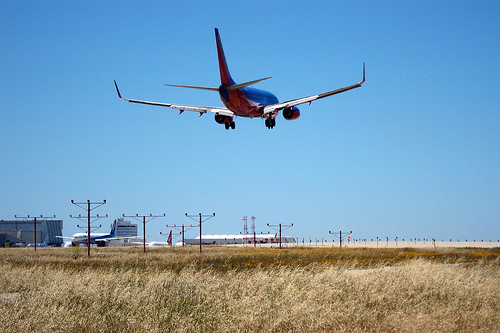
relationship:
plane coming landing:
[107, 26, 367, 131] [21, 251, 299, 281]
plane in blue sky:
[64, 19, 399, 140] [1, 0, 494, 232]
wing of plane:
[100, 60, 374, 124] [98, 24, 373, 151]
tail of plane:
[191, 30, 252, 79] [79, 24, 398, 150]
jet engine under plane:
[281, 107, 302, 119] [107, 26, 367, 131]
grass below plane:
[2, 242, 498, 330] [107, 26, 367, 131]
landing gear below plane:
[197, 110, 282, 138] [74, 33, 389, 137]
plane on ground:
[76, 229, 164, 249] [1, 243, 496, 331]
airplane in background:
[109, 27, 366, 129] [52, 142, 436, 251]